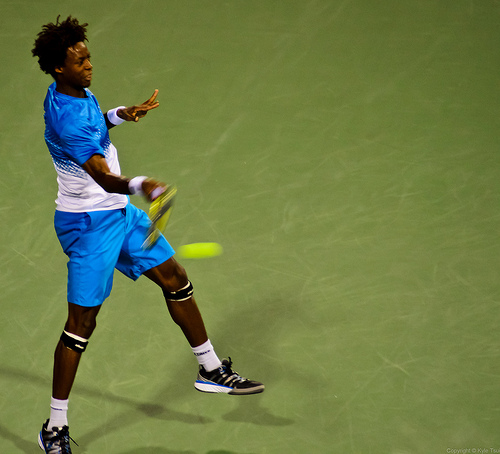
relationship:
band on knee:
[64, 320, 90, 352] [53, 342, 81, 374]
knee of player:
[70, 317, 96, 333] [11, 34, 251, 419]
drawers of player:
[53, 202, 175, 308] [15, 31, 270, 430]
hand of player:
[120, 80, 159, 120] [15, 31, 270, 430]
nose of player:
[85, 61, 92, 71] [26, 20, 275, 445]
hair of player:
[34, 12, 101, 59] [30, 20, 307, 397]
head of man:
[53, 25, 104, 77] [31, 14, 267, 454]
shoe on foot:
[193, 356, 265, 396] [189, 342, 317, 416]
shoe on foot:
[193, 356, 265, 396] [175, 336, 285, 409]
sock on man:
[174, 316, 282, 425] [34, 28, 223, 393]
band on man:
[106, 106, 126, 127] [43, 31, 277, 381]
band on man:
[128, 175, 148, 195] [31, 14, 267, 454]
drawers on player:
[53, 202, 175, 308] [0, 25, 317, 341]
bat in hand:
[139, 183, 178, 253] [109, 169, 189, 213]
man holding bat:
[21, 38, 274, 384] [115, 182, 215, 278]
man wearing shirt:
[31, 14, 267, 454] [25, 77, 166, 216]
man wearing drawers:
[31, 14, 267, 454] [35, 185, 207, 316]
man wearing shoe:
[31, 14, 267, 454] [175, 350, 286, 407]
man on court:
[31, 14, 267, 454] [25, 10, 481, 434]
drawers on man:
[53, 202, 175, 308] [31, 14, 267, 454]